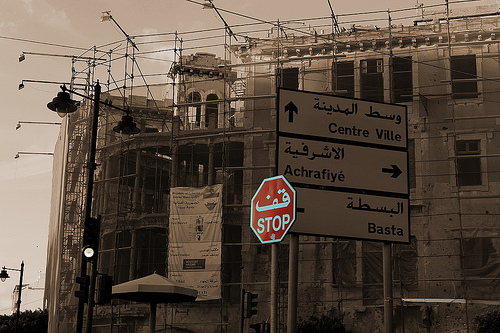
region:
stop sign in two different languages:
[244, 166, 302, 251]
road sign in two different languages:
[282, 94, 414, 249]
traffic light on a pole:
[77, 215, 99, 262]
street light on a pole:
[47, 80, 104, 135]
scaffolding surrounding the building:
[408, 13, 497, 280]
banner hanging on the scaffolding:
[166, 183, 228, 309]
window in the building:
[443, 53, 476, 107]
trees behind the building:
[2, 310, 49, 330]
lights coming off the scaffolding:
[99, 11, 139, 51]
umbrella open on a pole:
[113, 265, 200, 308]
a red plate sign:
[247, 170, 302, 244]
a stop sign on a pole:
[236, 171, 308, 250]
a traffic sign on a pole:
[245, 167, 305, 242]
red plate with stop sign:
[246, 172, 306, 249]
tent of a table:
[101, 266, 197, 312]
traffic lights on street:
[76, 208, 111, 325]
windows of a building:
[283, 50, 492, 105]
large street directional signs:
[262, 79, 424, 323]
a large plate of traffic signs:
[261, 68, 424, 329]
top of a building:
[16, 39, 239, 128]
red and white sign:
[244, 178, 315, 244]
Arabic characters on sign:
[249, 186, 302, 236]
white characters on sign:
[244, 181, 306, 248]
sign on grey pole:
[248, 184, 296, 326]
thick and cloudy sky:
[1, 4, 83, 119]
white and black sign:
[258, 91, 411, 236]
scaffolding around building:
[61, 56, 493, 331]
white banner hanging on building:
[156, 173, 226, 293]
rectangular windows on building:
[277, 45, 463, 105]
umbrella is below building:
[126, 263, 191, 303]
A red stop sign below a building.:
[247, 169, 303, 331]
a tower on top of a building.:
[161, 48, 241, 132]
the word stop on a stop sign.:
[252, 203, 292, 240]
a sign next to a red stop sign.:
[263, 82, 423, 247]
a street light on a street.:
[0, 253, 31, 323]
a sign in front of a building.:
[156, 161, 241, 317]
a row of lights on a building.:
[10, 27, 113, 167]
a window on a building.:
[445, 130, 492, 205]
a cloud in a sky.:
[125, 17, 200, 92]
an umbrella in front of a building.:
[101, 259, 206, 314]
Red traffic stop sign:
[248, 173, 299, 245]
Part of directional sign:
[275, 85, 417, 193]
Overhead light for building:
[15, 47, 63, 64]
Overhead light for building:
[13, 76, 59, 91]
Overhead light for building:
[5, 118, 56, 128]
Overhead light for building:
[8, 148, 50, 160]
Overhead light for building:
[90, 7, 132, 37]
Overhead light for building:
[191, 1, 235, 27]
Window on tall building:
[442, 130, 493, 195]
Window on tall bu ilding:
[388, 45, 420, 105]